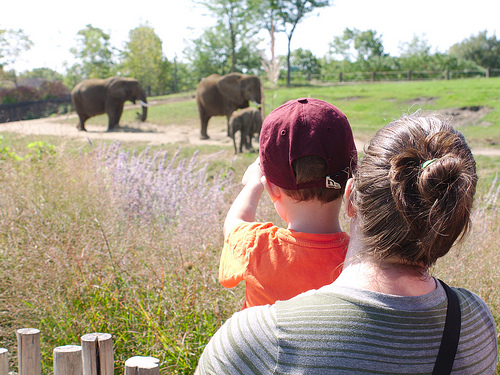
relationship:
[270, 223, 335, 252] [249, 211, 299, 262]
collar has edge of a collar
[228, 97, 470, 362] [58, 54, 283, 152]
boy and his mother watching elephants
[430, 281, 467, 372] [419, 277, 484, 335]
bag strap on shoulder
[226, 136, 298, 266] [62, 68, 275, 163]
boy is pointing at elephants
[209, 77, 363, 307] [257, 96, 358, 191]
boy has put on hat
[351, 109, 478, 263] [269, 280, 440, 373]
hair on back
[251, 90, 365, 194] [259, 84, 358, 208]
hat on boy's head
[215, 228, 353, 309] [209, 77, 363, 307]
an orange shirt on boy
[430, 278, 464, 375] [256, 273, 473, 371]
bag strap across back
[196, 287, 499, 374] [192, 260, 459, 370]
striped shirt on woman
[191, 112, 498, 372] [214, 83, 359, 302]
woman holding small boy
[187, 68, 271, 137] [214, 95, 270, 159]
an adult elephant next to elephant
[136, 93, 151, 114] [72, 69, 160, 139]
white tusk of elephant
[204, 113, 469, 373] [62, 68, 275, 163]
two people looking looking at elephants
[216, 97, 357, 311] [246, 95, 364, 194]
boy wearing baseball hat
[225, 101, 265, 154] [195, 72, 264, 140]
elephant and an adult elephant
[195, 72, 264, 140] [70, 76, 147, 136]
an adult elephant and elephant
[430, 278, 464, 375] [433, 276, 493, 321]
bag strap around woman's shoulder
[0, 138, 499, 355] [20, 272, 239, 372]
grass and bush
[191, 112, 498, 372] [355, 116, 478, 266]
woman has hair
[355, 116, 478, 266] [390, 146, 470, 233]
hair tied in bun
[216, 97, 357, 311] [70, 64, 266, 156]
boy pointing at elephants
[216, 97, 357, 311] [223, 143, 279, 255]
boy pointing with left hand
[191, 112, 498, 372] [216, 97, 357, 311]
woman holding boy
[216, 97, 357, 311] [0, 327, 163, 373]
boy looking over fence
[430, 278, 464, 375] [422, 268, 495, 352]
bag strap over woman's shoulder